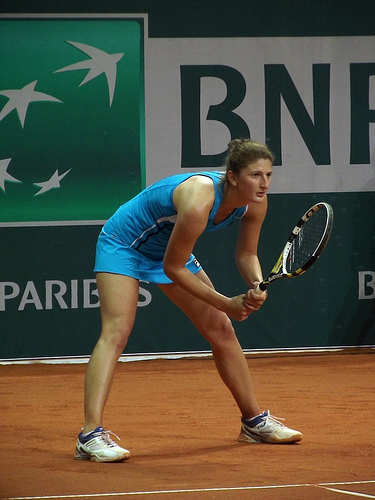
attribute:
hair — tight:
[217, 137, 274, 190]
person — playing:
[73, 137, 304, 462]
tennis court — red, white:
[0, 345, 375, 499]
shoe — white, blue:
[237, 412, 304, 443]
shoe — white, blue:
[72, 425, 131, 461]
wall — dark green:
[281, 93, 365, 169]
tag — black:
[104, 227, 166, 251]